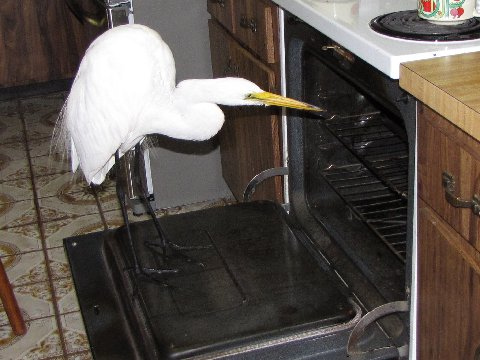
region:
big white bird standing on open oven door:
[51, 23, 325, 297]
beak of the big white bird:
[262, 91, 327, 112]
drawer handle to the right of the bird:
[440, 164, 478, 217]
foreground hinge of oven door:
[344, 296, 411, 358]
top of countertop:
[409, 51, 478, 102]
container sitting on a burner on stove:
[416, 0, 479, 28]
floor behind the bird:
[3, 194, 106, 226]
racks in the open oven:
[320, 111, 407, 257]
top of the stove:
[292, 0, 478, 59]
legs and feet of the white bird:
[105, 151, 213, 304]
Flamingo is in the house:
[36, 6, 285, 291]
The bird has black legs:
[35, 12, 321, 321]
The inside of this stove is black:
[264, 36, 418, 320]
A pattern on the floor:
[5, 106, 91, 242]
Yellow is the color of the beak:
[247, 71, 330, 130]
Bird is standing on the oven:
[40, 20, 303, 308]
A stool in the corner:
[4, 183, 48, 353]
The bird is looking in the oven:
[173, 56, 368, 169]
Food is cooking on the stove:
[378, 3, 479, 61]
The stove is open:
[57, 4, 419, 353]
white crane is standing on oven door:
[52, 14, 319, 296]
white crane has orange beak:
[60, 20, 321, 268]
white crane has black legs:
[50, 24, 222, 292]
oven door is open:
[46, 191, 371, 357]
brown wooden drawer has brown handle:
[413, 105, 478, 255]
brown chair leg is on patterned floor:
[0, 254, 33, 334]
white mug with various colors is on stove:
[415, 0, 476, 28]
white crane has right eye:
[243, 90, 254, 103]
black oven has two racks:
[309, 74, 414, 283]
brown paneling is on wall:
[3, 4, 127, 91]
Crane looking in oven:
[50, 23, 328, 310]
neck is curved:
[165, 75, 225, 141]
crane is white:
[49, 24, 327, 297]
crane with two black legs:
[114, 147, 212, 303]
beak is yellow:
[245, 90, 324, 112]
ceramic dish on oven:
[416, 0, 479, 26]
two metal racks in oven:
[316, 108, 409, 263]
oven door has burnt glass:
[152, 229, 245, 315]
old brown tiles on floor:
[0, 89, 236, 359]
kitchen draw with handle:
[408, 96, 477, 218]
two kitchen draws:
[70, 0, 322, 97]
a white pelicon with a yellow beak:
[45, 44, 327, 242]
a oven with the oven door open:
[263, 3, 462, 358]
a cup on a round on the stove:
[349, 0, 477, 43]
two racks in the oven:
[302, 61, 416, 296]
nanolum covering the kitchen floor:
[6, 94, 84, 310]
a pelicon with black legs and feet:
[36, 24, 324, 303]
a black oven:
[124, 24, 461, 358]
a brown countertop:
[421, 63, 477, 132]